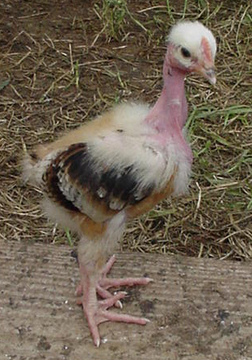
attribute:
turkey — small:
[19, 15, 219, 345]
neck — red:
[157, 80, 191, 117]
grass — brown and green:
[12, 33, 109, 98]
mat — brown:
[134, 252, 251, 358]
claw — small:
[91, 324, 102, 349]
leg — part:
[75, 232, 150, 347]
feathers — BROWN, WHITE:
[45, 136, 173, 220]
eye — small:
[181, 46, 192, 57]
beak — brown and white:
[202, 64, 217, 86]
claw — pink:
[78, 253, 155, 306]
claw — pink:
[77, 284, 156, 343]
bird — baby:
[96, 12, 215, 158]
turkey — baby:
[85, 28, 216, 200]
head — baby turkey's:
[169, 18, 219, 85]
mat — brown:
[167, 273, 209, 324]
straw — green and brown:
[225, 37, 246, 175]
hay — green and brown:
[199, 99, 251, 179]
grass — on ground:
[26, 41, 132, 114]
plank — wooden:
[0, 232, 250, 339]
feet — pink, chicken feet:
[57, 256, 153, 345]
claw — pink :
[73, 252, 153, 347]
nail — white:
[94, 336, 100, 348]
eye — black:
[178, 34, 193, 86]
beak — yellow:
[200, 69, 219, 87]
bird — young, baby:
[14, 12, 222, 347]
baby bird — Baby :
[22, 18, 221, 353]